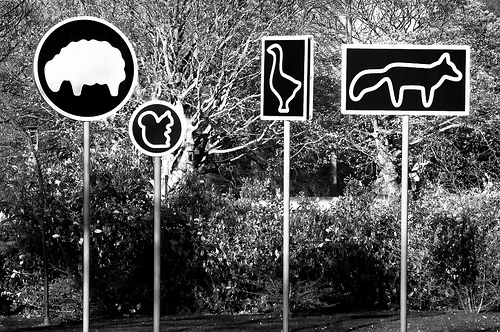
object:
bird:
[266, 42, 303, 114]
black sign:
[32, 15, 139, 122]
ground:
[343, 190, 382, 245]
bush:
[213, 197, 348, 304]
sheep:
[43, 38, 125, 98]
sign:
[127, 99, 186, 158]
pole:
[153, 158, 162, 291]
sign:
[341, 44, 470, 116]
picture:
[258, 34, 304, 122]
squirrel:
[138, 110, 176, 148]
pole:
[400, 112, 409, 329]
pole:
[282, 114, 289, 332]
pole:
[82, 116, 88, 330]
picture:
[127, 97, 184, 152]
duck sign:
[260, 34, 314, 121]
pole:
[59, 131, 184, 329]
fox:
[350, 52, 463, 107]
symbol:
[349, 52, 462, 109]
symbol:
[265, 44, 302, 113]